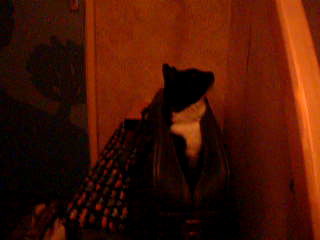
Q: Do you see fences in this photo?
A: No, there are no fences.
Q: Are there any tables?
A: Yes, there is a table.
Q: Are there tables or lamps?
A: Yes, there is a table.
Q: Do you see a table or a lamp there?
A: Yes, there is a table.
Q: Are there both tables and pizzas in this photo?
A: No, there is a table but no pizzas.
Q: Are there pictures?
A: No, there are no pictures.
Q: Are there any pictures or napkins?
A: No, there are no pictures or napkins.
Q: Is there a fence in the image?
A: No, there are no fences.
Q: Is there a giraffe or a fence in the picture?
A: No, there are no fences or giraffes.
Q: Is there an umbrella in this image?
A: No, there are no umbrellas.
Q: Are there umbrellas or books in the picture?
A: No, there are no umbrellas or books.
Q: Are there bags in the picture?
A: Yes, there is a bag.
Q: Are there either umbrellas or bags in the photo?
A: Yes, there is a bag.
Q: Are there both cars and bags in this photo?
A: No, there is a bag but no cars.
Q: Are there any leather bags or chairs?
A: Yes, there is a leather bag.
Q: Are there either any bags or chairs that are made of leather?
A: Yes, the bag is made of leather.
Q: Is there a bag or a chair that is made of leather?
A: Yes, the bag is made of leather.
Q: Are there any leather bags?
A: Yes, there is a bag that is made of leather.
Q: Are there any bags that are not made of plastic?
A: Yes, there is a bag that is made of leather.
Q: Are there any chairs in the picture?
A: No, there are no chairs.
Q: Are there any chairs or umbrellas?
A: No, there are no chairs or umbrellas.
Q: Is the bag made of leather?
A: Yes, the bag is made of leather.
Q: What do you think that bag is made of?
A: The bag is made of leather.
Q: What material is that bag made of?
A: The bag is made of leather.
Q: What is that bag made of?
A: The bag is made of leather.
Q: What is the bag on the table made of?
A: The bag is made of leather.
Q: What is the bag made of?
A: The bag is made of leather.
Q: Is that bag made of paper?
A: No, the bag is made of leather.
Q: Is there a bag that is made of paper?
A: No, there is a bag but it is made of leather.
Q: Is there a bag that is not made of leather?
A: No, there is a bag but it is made of leather.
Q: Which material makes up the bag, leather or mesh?
A: The bag is made of leather.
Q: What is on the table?
A: The bag is on the table.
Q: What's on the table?
A: The bag is on the table.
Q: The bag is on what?
A: The bag is on the table.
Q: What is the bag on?
A: The bag is on the table.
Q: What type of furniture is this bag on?
A: The bag is on the table.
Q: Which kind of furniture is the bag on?
A: The bag is on the table.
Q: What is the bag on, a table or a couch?
A: The bag is on a table.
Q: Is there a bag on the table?
A: Yes, there is a bag on the table.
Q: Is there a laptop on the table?
A: No, there is a bag on the table.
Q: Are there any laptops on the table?
A: No, there is a bag on the table.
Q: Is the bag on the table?
A: Yes, the bag is on the table.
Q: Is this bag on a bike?
A: No, the bag is on the table.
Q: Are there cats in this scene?
A: Yes, there is a cat.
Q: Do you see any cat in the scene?
A: Yes, there is a cat.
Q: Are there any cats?
A: Yes, there is a cat.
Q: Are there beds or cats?
A: Yes, there is a cat.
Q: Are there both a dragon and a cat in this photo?
A: No, there is a cat but no dragons.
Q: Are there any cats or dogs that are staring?
A: Yes, the cat is staring.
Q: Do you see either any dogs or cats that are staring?
A: Yes, the cat is staring.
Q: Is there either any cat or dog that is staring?
A: Yes, the cat is staring.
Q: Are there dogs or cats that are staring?
A: Yes, the cat is staring.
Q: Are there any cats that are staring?
A: Yes, there is a cat that is staring.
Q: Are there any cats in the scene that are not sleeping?
A: Yes, there is a cat that is staring.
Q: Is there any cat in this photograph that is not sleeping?
A: Yes, there is a cat that is staring.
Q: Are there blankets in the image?
A: No, there are no blankets.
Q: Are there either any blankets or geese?
A: No, there are no blankets or geese.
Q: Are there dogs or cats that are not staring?
A: No, there is a cat but it is staring.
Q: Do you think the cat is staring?
A: Yes, the cat is staring.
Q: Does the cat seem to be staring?
A: Yes, the cat is staring.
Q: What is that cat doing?
A: The cat is staring.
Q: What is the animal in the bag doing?
A: The cat is staring.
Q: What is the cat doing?
A: The cat is staring.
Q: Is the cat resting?
A: No, the cat is staring.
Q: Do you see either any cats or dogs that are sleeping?
A: No, there is a cat but it is staring.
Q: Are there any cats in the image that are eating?
A: No, there is a cat but it is staring.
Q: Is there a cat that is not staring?
A: No, there is a cat but it is staring.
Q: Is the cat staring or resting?
A: The cat is staring.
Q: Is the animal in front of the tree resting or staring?
A: The cat is staring.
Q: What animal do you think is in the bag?
A: The cat is in the bag.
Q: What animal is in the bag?
A: The cat is in the bag.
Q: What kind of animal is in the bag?
A: The animal is a cat.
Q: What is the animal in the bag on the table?
A: The animal is a cat.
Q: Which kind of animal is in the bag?
A: The animal is a cat.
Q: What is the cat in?
A: The cat is in the bag.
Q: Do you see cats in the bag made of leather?
A: Yes, there is a cat in the bag.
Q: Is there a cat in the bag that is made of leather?
A: Yes, there is a cat in the bag.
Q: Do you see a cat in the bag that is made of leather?
A: Yes, there is a cat in the bag.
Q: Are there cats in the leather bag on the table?
A: Yes, there is a cat in the bag.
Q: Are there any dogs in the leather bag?
A: No, there is a cat in the bag.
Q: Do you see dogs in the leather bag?
A: No, there is a cat in the bag.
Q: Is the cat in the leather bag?
A: Yes, the cat is in the bag.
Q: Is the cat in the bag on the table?
A: Yes, the cat is in the bag.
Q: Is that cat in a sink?
A: No, the cat is in the bag.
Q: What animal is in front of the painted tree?
A: The cat is in front of the tree.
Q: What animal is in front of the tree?
A: The cat is in front of the tree.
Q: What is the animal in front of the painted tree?
A: The animal is a cat.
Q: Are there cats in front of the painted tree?
A: Yes, there is a cat in front of the tree.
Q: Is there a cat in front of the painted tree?
A: Yes, there is a cat in front of the tree.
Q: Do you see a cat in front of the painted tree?
A: Yes, there is a cat in front of the tree.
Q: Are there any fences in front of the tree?
A: No, there is a cat in front of the tree.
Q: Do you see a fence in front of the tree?
A: No, there is a cat in front of the tree.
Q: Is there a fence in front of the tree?
A: No, there is a cat in front of the tree.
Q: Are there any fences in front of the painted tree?
A: No, there is a cat in front of the tree.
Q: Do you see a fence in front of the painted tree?
A: No, there is a cat in front of the tree.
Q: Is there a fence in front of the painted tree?
A: No, there is a cat in front of the tree.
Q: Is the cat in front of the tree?
A: Yes, the cat is in front of the tree.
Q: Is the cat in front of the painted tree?
A: Yes, the cat is in front of the tree.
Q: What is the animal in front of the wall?
A: The animal is a cat.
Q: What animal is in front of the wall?
A: The animal is a cat.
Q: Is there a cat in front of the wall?
A: Yes, there is a cat in front of the wall.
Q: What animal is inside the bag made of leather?
A: The cat is inside the bag.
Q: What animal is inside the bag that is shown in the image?
A: The animal is a cat.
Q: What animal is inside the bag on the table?
A: The animal is a cat.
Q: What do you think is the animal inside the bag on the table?
A: The animal is a cat.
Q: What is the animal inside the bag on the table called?
A: The animal is a cat.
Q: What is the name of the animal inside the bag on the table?
A: The animal is a cat.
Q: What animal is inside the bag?
A: The animal is a cat.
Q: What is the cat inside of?
A: The cat is inside the bag.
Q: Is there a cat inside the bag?
A: Yes, there is a cat inside the bag.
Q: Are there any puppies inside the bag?
A: No, there is a cat inside the bag.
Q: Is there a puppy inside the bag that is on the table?
A: No, there is a cat inside the bag.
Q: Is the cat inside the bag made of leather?
A: Yes, the cat is inside the bag.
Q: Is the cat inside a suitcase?
A: No, the cat is inside the bag.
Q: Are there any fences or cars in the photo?
A: No, there are no fences or cars.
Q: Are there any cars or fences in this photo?
A: No, there are no fences or cars.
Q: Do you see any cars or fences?
A: No, there are no fences or cars.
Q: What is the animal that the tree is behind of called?
A: The animal is a cat.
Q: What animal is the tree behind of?
A: The tree is behind the cat.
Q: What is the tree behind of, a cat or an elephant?
A: The tree is behind a cat.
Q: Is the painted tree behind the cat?
A: Yes, the tree is behind the cat.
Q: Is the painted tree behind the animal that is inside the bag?
A: Yes, the tree is behind the cat.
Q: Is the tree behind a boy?
A: No, the tree is behind the cat.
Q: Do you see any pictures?
A: No, there are no pictures.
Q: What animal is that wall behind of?
A: The wall is behind the cat.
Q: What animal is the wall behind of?
A: The wall is behind the cat.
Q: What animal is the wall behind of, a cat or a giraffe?
A: The wall is behind a cat.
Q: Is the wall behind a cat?
A: Yes, the wall is behind a cat.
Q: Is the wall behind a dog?
A: No, the wall is behind a cat.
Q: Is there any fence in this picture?
A: No, there are no fences.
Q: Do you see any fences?
A: No, there are no fences.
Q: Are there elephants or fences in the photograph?
A: No, there are no fences or elephants.